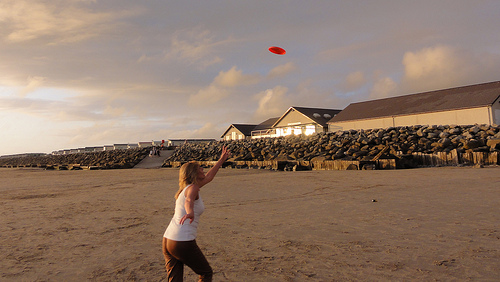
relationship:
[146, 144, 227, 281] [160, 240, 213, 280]
girl wears pants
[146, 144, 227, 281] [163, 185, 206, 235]
girl wears top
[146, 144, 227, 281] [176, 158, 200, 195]
girl has hair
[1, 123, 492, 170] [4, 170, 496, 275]
rocks near beach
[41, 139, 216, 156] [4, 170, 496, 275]
houses near beach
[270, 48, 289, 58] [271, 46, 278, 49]
frisbee has logo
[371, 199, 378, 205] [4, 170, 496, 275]
rock on beach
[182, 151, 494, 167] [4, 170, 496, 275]
barriers on beach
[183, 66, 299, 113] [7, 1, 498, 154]
cloud in sky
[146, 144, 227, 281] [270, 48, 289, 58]
girl throws frisbee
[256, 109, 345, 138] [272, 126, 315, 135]
house has windows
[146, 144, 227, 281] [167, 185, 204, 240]
girl wears shirt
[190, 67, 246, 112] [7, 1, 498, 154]
cloud in sky